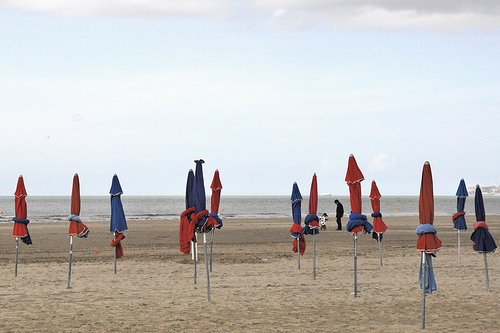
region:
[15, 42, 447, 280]
this is along a coast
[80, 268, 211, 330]
the sand here is very light brown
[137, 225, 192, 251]
the sand here is dark brown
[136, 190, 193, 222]
the water is dark blue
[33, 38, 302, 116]
the sky is partly cloudy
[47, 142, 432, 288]
these are umbrellas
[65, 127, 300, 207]
the umbrellas are blue and red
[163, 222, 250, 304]
the umbrellas poles are metal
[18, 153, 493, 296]
a whole beach full of umbrellas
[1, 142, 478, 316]
none of the umbrellas are open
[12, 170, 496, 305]
they are all red with blue ties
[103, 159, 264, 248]
or they are blue with red ties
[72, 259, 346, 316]
the beach is brown & sandy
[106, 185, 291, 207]
the surf is very calm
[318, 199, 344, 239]
a man & a little girl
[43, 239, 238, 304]
the umbrellas have metal posts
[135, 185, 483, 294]
it appears to be a chilly day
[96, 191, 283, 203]
the sea is grey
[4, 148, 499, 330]
series of folded umbrellas on the beach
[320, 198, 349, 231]
man and child standing on the beach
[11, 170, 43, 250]
folded up red umbrella in the sand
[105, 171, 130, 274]
folded up medium blue umbrella in the sand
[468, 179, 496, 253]
folded up dark blue umbrella in the sand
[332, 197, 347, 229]
person wearing all black clothing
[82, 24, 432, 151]
light blue sky with wispy white clouds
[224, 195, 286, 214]
calm blue gray water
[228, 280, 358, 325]
sandy beach area filled with umbrellas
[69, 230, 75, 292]
tall silver poles holding umbrellas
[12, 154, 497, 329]
the empty umbrellas at the beach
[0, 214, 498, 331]
the sand at the beach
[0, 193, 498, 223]
the body of water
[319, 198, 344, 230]
the people on the sand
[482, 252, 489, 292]
the pole for the umbrella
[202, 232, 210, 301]
the pole for the umbrella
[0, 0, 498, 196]
the clouds in the sky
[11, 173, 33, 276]
the closed umbrella on the sand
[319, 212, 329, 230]
the small person on the sand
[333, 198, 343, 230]
the person dressed in all black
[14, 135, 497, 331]
beach umbrellas folded on beach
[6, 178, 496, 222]
a calm ocean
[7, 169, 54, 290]
red umbrella with blue strap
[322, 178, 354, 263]
man and child on the beach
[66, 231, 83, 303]
pole of the umbrella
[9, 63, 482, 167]
cloudy sky in the horizon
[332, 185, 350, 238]
man wearing black coat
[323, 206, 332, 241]
xhild wearing white coat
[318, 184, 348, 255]
people enjoying the beach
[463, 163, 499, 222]
the shore with buildings